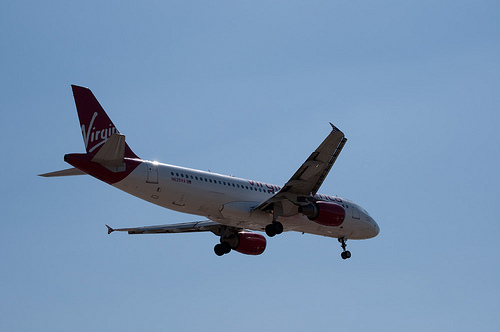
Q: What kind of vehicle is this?
A: Airplane.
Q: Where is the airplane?
A: Sky.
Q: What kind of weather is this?
A: Clear and sunny.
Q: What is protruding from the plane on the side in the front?
A: Wings.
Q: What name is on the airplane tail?
A: Virgin.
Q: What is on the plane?
A: Logo.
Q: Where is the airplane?
A: In the sky.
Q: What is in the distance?
A: Blue sky.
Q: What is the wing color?
A: Black.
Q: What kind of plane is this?
A: Passenger.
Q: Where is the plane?
A: In the sky.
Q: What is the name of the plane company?
A: Virgin airlines.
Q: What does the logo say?
A: Virgin airways.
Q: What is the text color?
A: White.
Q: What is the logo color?
A: Red and white.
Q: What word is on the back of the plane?
A: Virgin.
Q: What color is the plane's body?
A: White.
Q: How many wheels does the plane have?
A: 6.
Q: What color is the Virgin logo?
A: White.